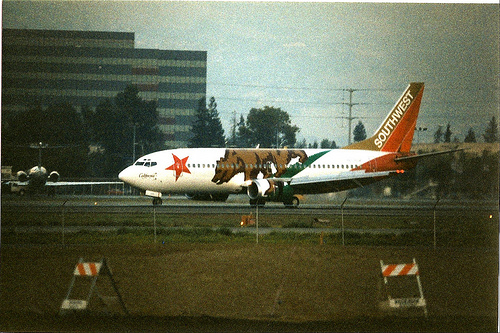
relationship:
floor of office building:
[0, 54, 209, 79] [2, 26, 206, 178]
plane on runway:
[8, 146, 70, 208] [21, 187, 118, 208]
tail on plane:
[343, 76, 424, 160] [118, 83, 473, 205]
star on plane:
[164, 153, 193, 183] [115, 79, 425, 209]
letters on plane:
[372, 83, 412, 149] [122, 73, 469, 220]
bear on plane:
[212, 143, 346, 184] [96, 133, 413, 234]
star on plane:
[164, 150, 199, 186] [80, 74, 455, 194]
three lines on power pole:
[253, 81, 483, 123] [343, 85, 357, 147]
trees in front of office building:
[113, 80, 173, 156] [2, 23, 206, 178]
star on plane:
[164, 153, 193, 183] [118, 83, 473, 205]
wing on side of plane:
[272, 166, 406, 196] [118, 83, 473, 205]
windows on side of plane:
[198, 139, 398, 181] [102, 76, 459, 199]